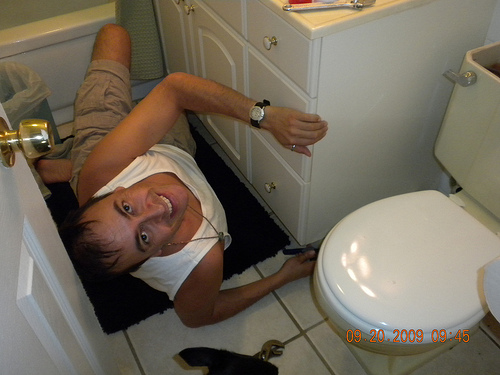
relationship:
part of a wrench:
[265, 347, 267, 352] [256, 339, 286, 361]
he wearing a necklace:
[19, 20, 322, 327] [186, 202, 231, 247]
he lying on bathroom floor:
[19, 20, 322, 327] [128, 271, 315, 369]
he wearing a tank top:
[19, 20, 322, 327] [109, 141, 231, 295]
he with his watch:
[19, 20, 322, 327] [249, 99, 271, 129]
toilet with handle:
[308, 41, 485, 373] [438, 60, 480, 90]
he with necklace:
[19, 20, 322, 327] [134, 192, 226, 250]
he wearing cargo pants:
[19, 20, 322, 327] [43, 59, 197, 197]